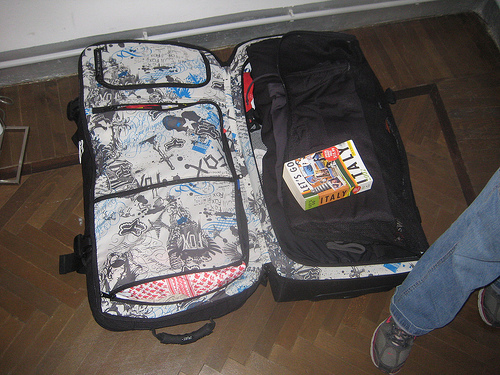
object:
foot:
[370, 315, 416, 374]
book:
[280, 138, 374, 211]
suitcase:
[55, 26, 440, 345]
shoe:
[368, 302, 417, 372]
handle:
[151, 316, 217, 345]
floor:
[2, 10, 500, 374]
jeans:
[382, 162, 499, 339]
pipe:
[2, 0, 431, 70]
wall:
[1, 1, 482, 86]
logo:
[185, 148, 228, 183]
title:
[335, 147, 367, 186]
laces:
[388, 324, 411, 349]